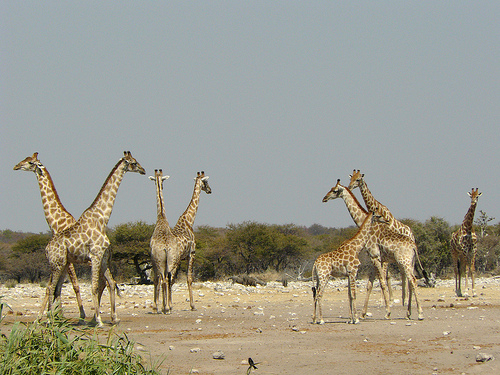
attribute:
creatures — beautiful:
[284, 156, 433, 344]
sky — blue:
[193, 38, 335, 167]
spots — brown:
[320, 248, 352, 281]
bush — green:
[17, 311, 98, 372]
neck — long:
[88, 156, 135, 236]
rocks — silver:
[207, 262, 251, 311]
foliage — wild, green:
[17, 303, 116, 373]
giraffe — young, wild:
[284, 204, 401, 356]